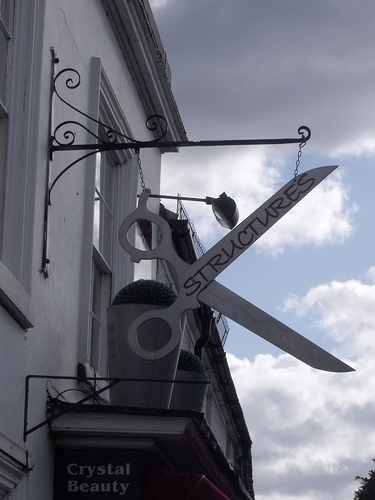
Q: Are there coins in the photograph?
A: No, there are no coins.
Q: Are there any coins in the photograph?
A: No, there are no coins.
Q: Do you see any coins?
A: No, there are no coins.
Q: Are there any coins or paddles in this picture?
A: No, there are no coins or paddles.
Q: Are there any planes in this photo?
A: No, there are no planes.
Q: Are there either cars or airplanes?
A: No, there are no airplanes or cars.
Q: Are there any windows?
A: Yes, there is a window.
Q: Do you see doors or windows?
A: Yes, there is a window.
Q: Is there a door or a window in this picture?
A: Yes, there is a window.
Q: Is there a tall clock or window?
A: Yes, there is a tall window.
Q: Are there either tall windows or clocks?
A: Yes, there is a tall window.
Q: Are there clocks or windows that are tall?
A: Yes, the window is tall.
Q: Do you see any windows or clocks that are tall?
A: Yes, the window is tall.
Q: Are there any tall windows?
A: Yes, there is a tall window.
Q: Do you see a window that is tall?
A: Yes, there is a window that is tall.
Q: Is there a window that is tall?
A: Yes, there is a window that is tall.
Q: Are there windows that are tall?
A: Yes, there is a window that is tall.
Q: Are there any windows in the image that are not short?
A: Yes, there is a tall window.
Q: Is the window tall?
A: Yes, the window is tall.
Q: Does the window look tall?
A: Yes, the window is tall.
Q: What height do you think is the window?
A: The window is tall.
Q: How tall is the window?
A: The window is tall.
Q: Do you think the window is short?
A: No, the window is tall.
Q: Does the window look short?
A: No, the window is tall.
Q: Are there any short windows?
A: No, there is a window but it is tall.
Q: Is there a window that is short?
A: No, there is a window but it is tall.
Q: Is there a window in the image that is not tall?
A: No, there is a window but it is tall.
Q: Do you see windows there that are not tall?
A: No, there is a window but it is tall.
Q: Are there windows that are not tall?
A: No, there is a window but it is tall.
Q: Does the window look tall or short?
A: The window is tall.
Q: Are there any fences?
A: No, there are no fences.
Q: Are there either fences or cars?
A: No, there are no fences or cars.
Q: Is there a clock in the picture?
A: No, there are no clocks.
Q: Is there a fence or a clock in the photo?
A: No, there are no clocks or fences.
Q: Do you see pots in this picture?
A: Yes, there is a pot.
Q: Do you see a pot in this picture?
A: Yes, there is a pot.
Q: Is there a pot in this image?
A: Yes, there is a pot.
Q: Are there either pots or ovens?
A: Yes, there is a pot.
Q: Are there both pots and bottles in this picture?
A: No, there is a pot but no bottles.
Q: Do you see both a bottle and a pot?
A: No, there is a pot but no bottles.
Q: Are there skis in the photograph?
A: No, there are no skis.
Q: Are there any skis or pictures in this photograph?
A: No, there are no skis or pictures.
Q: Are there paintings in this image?
A: No, there are no paintings.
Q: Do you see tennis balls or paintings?
A: No, there are no paintings or tennis balls.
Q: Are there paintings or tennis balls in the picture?
A: No, there are no paintings or tennis balls.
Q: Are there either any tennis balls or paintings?
A: No, there are no paintings or tennis balls.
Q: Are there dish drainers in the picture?
A: No, there are no dish drainers.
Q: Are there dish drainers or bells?
A: No, there are no dish drainers or bells.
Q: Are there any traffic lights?
A: No, there are no traffic lights.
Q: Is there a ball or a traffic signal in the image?
A: No, there are no traffic lights or balls.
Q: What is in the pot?
A: The plant is in the pot.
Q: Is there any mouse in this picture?
A: No, there are no computer mice.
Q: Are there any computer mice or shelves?
A: No, there are no computer mice or shelves.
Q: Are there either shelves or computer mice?
A: No, there are no computer mice or shelves.